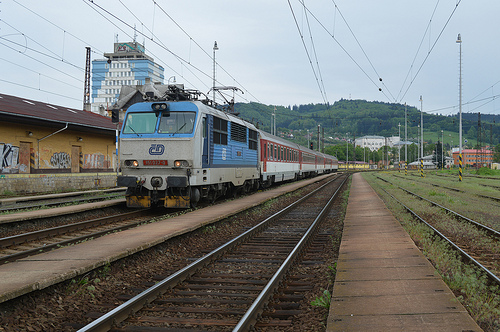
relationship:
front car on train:
[116, 97, 261, 193] [115, 100, 340, 210]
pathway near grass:
[326, 170, 473, 330] [360, 158, 498, 315]